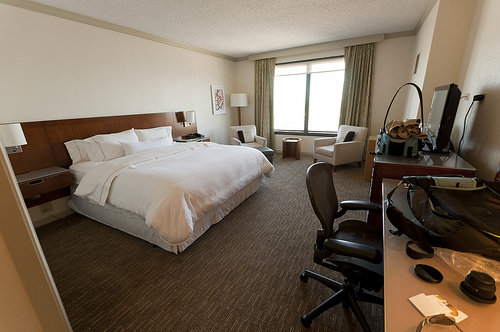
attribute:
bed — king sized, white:
[67, 144, 261, 255]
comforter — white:
[94, 142, 273, 243]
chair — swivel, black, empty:
[299, 160, 383, 329]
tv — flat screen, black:
[425, 85, 455, 151]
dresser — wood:
[365, 140, 474, 224]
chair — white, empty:
[312, 124, 366, 170]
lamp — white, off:
[228, 94, 249, 130]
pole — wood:
[237, 106, 241, 126]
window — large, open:
[271, 56, 345, 135]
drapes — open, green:
[253, 41, 374, 150]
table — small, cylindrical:
[280, 137, 301, 161]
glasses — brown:
[416, 312, 464, 331]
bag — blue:
[376, 80, 423, 157]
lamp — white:
[2, 122, 30, 156]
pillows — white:
[59, 127, 171, 159]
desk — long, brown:
[382, 177, 498, 331]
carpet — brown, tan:
[39, 149, 377, 327]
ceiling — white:
[38, 1, 437, 58]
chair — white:
[231, 125, 267, 146]